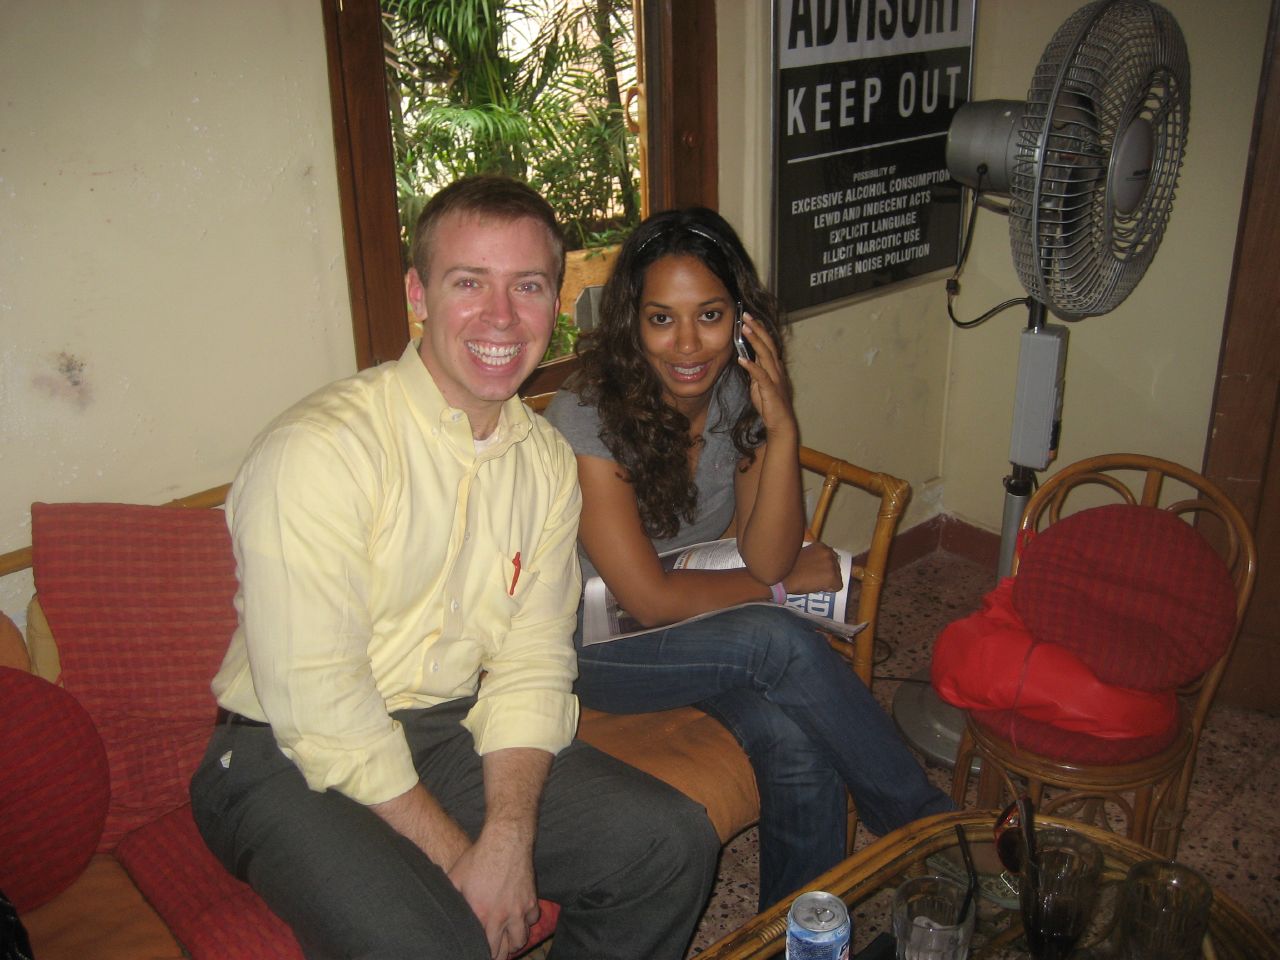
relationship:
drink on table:
[762, 889, 892, 960] [731, 770, 1217, 958]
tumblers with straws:
[925, 742, 1143, 932] [915, 772, 1061, 927]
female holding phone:
[587, 202, 1008, 939] [722, 297, 773, 380]